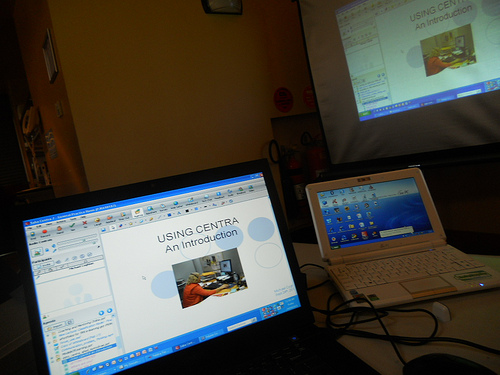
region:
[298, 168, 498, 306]
A small white laptop computer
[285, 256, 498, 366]
Some black cables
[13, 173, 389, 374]
A black laptop with a computer program open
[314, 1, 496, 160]
A presentation projected onto a screen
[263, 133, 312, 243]
A red fire extinguisher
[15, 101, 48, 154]
An off white wall phone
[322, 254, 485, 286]
A keyboard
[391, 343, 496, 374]
A black computer mouse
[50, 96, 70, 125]
A light switch on the wall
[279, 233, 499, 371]
A white table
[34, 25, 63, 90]
white picture hanging on wall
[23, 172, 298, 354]
website displayed on computer monitor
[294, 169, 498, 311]
small white laptop sitting on table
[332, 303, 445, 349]
black electric cords for computer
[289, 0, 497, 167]
large projection screen on wall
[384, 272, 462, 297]
small white mouse pad on laptop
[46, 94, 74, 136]
small white light switch on wall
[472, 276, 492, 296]
power light on front of laptop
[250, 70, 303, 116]
red sticker on wall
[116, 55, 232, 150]
white paint on wall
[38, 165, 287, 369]
screen of a laptop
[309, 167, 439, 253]
small screen of netbook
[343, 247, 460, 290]
keyboard of a netbook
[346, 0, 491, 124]
images on a large screen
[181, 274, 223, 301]
woman at a desk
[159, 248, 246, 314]
image of woman using a computer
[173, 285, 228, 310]
orange long sleeve shirt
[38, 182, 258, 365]
email client open on screen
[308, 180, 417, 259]
desktop background open with icons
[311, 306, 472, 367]
black cords on table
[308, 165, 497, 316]
small white plastic laptop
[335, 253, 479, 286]
keyboard of white laptop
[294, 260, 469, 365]
black tangled cables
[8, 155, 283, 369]
screen of a black laptop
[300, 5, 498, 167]
white pull down projector screen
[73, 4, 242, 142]
bare blank white wall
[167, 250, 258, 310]
picture of a person on a laptop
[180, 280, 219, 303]
person wearing orange shirt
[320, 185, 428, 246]
blue desktop background on laptop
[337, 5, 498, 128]
laptop screen projected on wall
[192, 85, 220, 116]
part of a wall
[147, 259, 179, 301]
part of a monitor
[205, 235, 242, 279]
part of a laptop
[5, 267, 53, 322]
edge of a latop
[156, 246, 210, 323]
part of a frame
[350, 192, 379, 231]
part of a monitor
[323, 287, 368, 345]
part of a paper